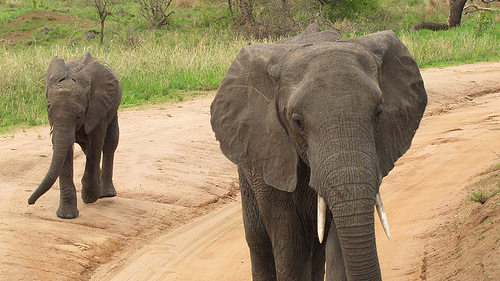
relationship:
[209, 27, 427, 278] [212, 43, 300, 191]
elephant has right ear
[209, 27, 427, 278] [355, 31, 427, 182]
elephant has left ear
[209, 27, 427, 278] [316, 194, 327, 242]
elephant has tusk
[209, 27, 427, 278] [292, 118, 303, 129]
elephant has eye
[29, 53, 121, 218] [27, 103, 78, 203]
elephant has trunk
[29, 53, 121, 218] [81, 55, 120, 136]
elephant has left ear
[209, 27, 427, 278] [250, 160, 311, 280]
elephant has front leg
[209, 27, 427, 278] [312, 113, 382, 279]
elephant has trunk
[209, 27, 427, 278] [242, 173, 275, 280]
elephant has leg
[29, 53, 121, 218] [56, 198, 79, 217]
elephant has foot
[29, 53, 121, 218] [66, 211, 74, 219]
elephant has toe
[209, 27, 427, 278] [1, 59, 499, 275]
elephant on top of pathway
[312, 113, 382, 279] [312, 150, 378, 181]
trunk has line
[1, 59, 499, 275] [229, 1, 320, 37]
pathway as bush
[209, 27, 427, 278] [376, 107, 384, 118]
elephant has left eye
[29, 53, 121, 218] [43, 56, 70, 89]
elephant has right ear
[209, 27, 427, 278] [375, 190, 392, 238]
elephant has left tusk